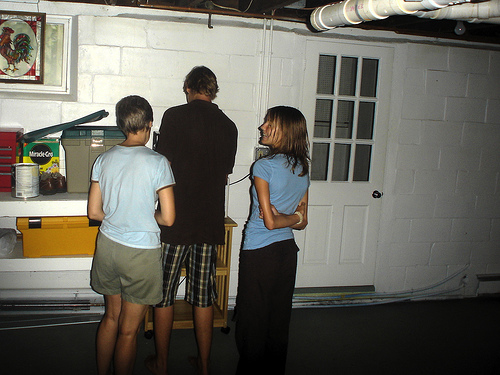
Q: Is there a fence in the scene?
A: No, there are no fences.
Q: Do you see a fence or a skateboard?
A: No, there are no fences or skateboards.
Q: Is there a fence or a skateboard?
A: No, there are no fences or skateboards.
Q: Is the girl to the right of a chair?
A: No, the girl is to the right of the container.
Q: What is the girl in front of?
A: The girl is in front of the door.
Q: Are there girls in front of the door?
A: Yes, there is a girl in front of the door.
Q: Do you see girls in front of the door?
A: Yes, there is a girl in front of the door.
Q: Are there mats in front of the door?
A: No, there is a girl in front of the door.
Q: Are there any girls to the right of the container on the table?
A: Yes, there is a girl to the right of the container.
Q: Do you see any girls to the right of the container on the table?
A: Yes, there is a girl to the right of the container.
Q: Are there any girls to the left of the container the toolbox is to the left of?
A: No, the girl is to the right of the container.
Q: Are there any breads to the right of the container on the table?
A: No, there is a girl to the right of the container.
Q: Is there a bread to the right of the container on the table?
A: No, there is a girl to the right of the container.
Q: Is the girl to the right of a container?
A: Yes, the girl is to the right of a container.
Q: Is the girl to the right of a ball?
A: No, the girl is to the right of a container.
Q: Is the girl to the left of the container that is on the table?
A: No, the girl is to the right of the container.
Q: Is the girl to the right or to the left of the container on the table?
A: The girl is to the right of the container.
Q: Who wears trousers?
A: The girl wears trousers.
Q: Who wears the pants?
A: The girl wears trousers.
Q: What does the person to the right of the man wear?
A: The girl wears trousers.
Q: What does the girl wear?
A: The girl wears trousers.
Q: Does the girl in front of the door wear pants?
A: Yes, the girl wears pants.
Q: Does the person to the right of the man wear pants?
A: Yes, the girl wears pants.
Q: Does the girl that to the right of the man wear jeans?
A: No, the girl wears pants.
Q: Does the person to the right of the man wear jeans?
A: No, the girl wears pants.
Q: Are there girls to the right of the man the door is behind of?
A: Yes, there is a girl to the right of the man.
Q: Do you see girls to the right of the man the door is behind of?
A: Yes, there is a girl to the right of the man.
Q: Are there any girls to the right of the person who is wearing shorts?
A: Yes, there is a girl to the right of the man.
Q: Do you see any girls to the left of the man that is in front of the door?
A: No, the girl is to the right of the man.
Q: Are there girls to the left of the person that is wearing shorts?
A: No, the girl is to the right of the man.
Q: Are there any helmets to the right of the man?
A: No, there is a girl to the right of the man.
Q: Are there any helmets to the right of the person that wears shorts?
A: No, there is a girl to the right of the man.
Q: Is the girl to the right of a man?
A: Yes, the girl is to the right of a man.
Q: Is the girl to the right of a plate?
A: No, the girl is to the right of a man.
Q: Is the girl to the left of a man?
A: No, the girl is to the right of a man.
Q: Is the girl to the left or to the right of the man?
A: The girl is to the right of the man.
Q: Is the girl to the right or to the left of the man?
A: The girl is to the right of the man.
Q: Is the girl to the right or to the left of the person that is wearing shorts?
A: The girl is to the right of the man.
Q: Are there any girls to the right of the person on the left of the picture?
A: Yes, there is a girl to the right of the person.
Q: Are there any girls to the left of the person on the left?
A: No, the girl is to the right of the person.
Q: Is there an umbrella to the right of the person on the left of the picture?
A: No, there is a girl to the right of the person.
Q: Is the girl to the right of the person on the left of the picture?
A: Yes, the girl is to the right of the person.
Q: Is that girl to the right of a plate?
A: No, the girl is to the right of the person.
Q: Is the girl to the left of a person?
A: No, the girl is to the right of a person.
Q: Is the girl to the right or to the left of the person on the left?
A: The girl is to the right of the person.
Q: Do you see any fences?
A: No, there are no fences.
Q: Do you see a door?
A: Yes, there is a door.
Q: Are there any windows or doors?
A: Yes, there is a door.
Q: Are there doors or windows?
A: Yes, there is a door.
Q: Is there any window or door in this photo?
A: Yes, there is a door.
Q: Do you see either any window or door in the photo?
A: Yes, there is a door.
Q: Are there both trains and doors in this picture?
A: No, there is a door but no trains.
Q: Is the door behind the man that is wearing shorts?
A: Yes, the door is behind the man.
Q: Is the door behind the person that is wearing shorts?
A: Yes, the door is behind the man.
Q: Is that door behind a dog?
A: No, the door is behind the man.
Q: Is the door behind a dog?
A: No, the door is behind a person.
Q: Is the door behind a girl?
A: Yes, the door is behind a girl.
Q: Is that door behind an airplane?
A: No, the door is behind a girl.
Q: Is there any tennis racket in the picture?
A: No, there are no rackets.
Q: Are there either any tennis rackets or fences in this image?
A: No, there are no tennis rackets or fences.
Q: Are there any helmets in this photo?
A: No, there are no helmets.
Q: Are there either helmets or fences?
A: No, there are no helmets or fences.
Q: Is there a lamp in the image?
A: No, there are no lamps.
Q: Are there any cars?
A: No, there are no cars.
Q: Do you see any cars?
A: No, there are no cars.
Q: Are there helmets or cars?
A: No, there are no cars or helmets.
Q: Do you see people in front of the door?
A: Yes, there is a person in front of the door.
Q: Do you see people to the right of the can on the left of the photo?
A: Yes, there is a person to the right of the can.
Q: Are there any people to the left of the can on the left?
A: No, the person is to the right of the can.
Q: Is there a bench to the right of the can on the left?
A: No, there is a person to the right of the can.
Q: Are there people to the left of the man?
A: Yes, there is a person to the left of the man.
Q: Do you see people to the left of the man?
A: Yes, there is a person to the left of the man.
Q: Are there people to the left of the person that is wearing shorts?
A: Yes, there is a person to the left of the man.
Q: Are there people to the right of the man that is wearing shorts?
A: No, the person is to the left of the man.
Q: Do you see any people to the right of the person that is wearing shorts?
A: No, the person is to the left of the man.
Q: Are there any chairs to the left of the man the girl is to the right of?
A: No, there is a person to the left of the man.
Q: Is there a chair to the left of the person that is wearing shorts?
A: No, there is a person to the left of the man.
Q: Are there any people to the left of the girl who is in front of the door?
A: Yes, there is a person to the left of the girl.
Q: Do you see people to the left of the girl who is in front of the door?
A: Yes, there is a person to the left of the girl.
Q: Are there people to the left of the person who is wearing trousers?
A: Yes, there is a person to the left of the girl.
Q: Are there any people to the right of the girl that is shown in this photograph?
A: No, the person is to the left of the girl.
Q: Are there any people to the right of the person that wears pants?
A: No, the person is to the left of the girl.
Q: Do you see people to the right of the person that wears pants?
A: No, the person is to the left of the girl.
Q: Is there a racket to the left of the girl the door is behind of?
A: No, there is a person to the left of the girl.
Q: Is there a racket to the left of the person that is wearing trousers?
A: No, there is a person to the left of the girl.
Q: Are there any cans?
A: Yes, there is a can.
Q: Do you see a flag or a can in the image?
A: Yes, there is a can.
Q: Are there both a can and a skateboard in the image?
A: No, there is a can but no skateboards.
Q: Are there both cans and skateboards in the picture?
A: No, there is a can but no skateboards.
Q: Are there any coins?
A: No, there are no coins.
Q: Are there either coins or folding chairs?
A: No, there are no coins or folding chairs.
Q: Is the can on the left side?
A: Yes, the can is on the left of the image.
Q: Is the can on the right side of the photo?
A: No, the can is on the left of the image.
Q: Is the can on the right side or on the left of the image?
A: The can is on the left of the image.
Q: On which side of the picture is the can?
A: The can is on the left of the image.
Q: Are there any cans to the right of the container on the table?
A: No, the can is to the left of the container.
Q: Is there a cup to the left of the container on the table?
A: No, there is a can to the left of the container.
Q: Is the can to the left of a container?
A: Yes, the can is to the left of a container.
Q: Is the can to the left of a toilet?
A: No, the can is to the left of a container.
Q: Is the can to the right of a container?
A: No, the can is to the left of a container.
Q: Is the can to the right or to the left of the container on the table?
A: The can is to the left of the container.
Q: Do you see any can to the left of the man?
A: Yes, there is a can to the left of the man.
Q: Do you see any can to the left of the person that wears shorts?
A: Yes, there is a can to the left of the man.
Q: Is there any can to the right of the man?
A: No, the can is to the left of the man.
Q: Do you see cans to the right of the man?
A: No, the can is to the left of the man.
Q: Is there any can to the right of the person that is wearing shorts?
A: No, the can is to the left of the man.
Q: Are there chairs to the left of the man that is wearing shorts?
A: No, there is a can to the left of the man.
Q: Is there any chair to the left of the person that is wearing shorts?
A: No, there is a can to the left of the man.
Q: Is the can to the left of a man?
A: Yes, the can is to the left of a man.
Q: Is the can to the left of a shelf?
A: No, the can is to the left of a man.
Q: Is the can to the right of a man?
A: No, the can is to the left of a man.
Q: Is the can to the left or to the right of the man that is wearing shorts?
A: The can is to the left of the man.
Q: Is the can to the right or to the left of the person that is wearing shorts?
A: The can is to the left of the man.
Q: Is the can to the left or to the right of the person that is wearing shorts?
A: The can is to the left of the man.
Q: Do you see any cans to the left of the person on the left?
A: Yes, there is a can to the left of the person.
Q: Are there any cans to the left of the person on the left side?
A: Yes, there is a can to the left of the person.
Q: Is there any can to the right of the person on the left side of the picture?
A: No, the can is to the left of the person.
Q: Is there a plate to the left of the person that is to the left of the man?
A: No, there is a can to the left of the person.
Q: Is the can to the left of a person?
A: Yes, the can is to the left of a person.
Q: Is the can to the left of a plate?
A: No, the can is to the left of a person.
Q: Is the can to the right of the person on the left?
A: No, the can is to the left of the person.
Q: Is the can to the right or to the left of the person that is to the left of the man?
A: The can is to the left of the person.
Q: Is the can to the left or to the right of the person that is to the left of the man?
A: The can is to the left of the person.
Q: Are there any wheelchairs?
A: No, there are no wheelchairs.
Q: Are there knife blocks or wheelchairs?
A: No, there are no wheelchairs or knife blocks.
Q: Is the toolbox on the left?
A: Yes, the toolbox is on the left of the image.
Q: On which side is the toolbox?
A: The toolbox is on the left of the image.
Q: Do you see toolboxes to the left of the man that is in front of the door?
A: Yes, there is a toolbox to the left of the man.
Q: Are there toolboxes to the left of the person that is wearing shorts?
A: Yes, there is a toolbox to the left of the man.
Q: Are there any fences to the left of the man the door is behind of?
A: No, there is a toolbox to the left of the man.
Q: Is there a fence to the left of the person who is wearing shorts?
A: No, there is a toolbox to the left of the man.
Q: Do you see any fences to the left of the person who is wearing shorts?
A: No, there is a toolbox to the left of the man.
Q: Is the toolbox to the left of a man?
A: Yes, the toolbox is to the left of a man.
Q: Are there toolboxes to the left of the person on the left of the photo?
A: Yes, there is a toolbox to the left of the person.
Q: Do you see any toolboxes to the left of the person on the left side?
A: Yes, there is a toolbox to the left of the person.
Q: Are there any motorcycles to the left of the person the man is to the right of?
A: No, there is a toolbox to the left of the person.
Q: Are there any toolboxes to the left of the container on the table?
A: Yes, there is a toolbox to the left of the container.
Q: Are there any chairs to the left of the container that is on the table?
A: No, there is a toolbox to the left of the container.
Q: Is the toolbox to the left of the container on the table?
A: Yes, the toolbox is to the left of the container.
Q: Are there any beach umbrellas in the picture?
A: No, there are no beach umbrellas.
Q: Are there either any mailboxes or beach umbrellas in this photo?
A: No, there are no beach umbrellas or mailboxes.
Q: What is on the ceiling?
A: The pipe is on the ceiling.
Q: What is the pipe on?
A: The pipe is on the ceiling.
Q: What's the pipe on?
A: The pipe is on the ceiling.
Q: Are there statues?
A: No, there are no statues.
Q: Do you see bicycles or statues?
A: No, there are no statues or bicycles.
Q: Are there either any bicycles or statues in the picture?
A: No, there are no statues or bicycles.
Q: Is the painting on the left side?
A: Yes, the painting is on the left of the image.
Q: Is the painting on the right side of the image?
A: No, the painting is on the left of the image.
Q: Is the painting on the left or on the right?
A: The painting is on the left of the image.